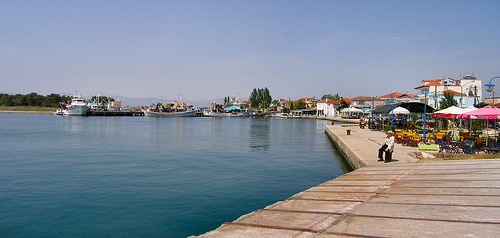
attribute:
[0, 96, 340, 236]
water — blue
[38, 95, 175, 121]
ship — white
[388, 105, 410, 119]
umbrella — white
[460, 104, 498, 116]
umbrella — pink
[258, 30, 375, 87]
sky — blue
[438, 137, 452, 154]
chair — blue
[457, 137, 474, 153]
chair — blue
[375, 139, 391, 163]
pants — black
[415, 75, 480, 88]
roof — red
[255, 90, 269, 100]
leaves — green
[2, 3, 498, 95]
sky — blue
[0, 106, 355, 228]
water — calm, body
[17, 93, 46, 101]
trees — clumped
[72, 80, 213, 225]
water — blue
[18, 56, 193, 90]
clouds — white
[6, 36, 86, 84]
clouds — white